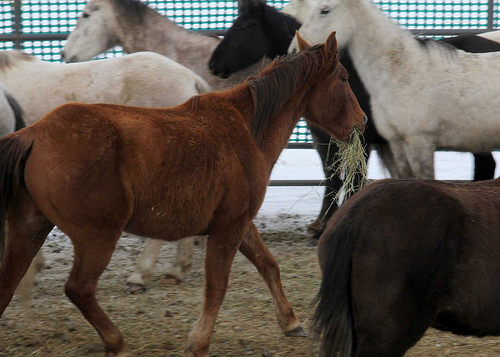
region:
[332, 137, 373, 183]
green grass hanging from horse's mouth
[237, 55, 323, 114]
brown horse's mane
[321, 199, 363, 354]
dark brown horse's tail on right of photo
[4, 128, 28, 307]
brown tail of horse on front of picture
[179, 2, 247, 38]
blue fencing in far back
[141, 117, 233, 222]
shaggy fur on horse's stomache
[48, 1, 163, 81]
back left white horse facing left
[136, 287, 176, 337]
light brown dirt on ground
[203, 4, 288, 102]
black horse in back right of photo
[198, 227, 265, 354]
right leg of front horse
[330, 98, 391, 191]
horse is carrying hay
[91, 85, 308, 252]
brown horse still has winter coat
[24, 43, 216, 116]
horse is white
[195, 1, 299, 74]
horse is dark brown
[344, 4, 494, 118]
horse is grayish color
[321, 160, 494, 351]
back side of the horse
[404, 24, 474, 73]
grayish horse has black mane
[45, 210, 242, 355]
horses are in the dirt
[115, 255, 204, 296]
hoofs of a horse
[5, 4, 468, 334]
group of horses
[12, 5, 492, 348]
A multicolored group of horses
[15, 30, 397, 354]
A brown horse eating hay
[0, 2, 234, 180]
Two white horses standing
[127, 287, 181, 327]
Small rocks on the ground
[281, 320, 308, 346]
The horse has grey hooves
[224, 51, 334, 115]
A brown horse's mane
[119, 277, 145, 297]
The white horse has brown hooves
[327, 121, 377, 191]
Hay in the horse's mouth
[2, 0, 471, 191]
A metal gate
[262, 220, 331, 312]
Dirt beneath the horses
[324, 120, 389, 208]
The horse has hay in its mouth.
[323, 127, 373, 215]
The hay is light green.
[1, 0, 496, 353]
A group of horses.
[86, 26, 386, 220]
This horse is reddish brown.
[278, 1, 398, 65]
This horse is white.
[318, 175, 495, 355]
This horse is brown.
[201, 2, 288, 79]
This horse is black.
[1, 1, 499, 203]
A fence is in the background.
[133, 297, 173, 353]
The ground is brown.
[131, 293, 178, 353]
The ground is dirt.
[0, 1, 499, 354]
six horses in a barn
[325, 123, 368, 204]
hay in the horse's mouth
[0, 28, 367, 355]
a brown horse among other horses in a barn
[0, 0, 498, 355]
white, brown, and black horses in a barn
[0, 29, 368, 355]
a brown horse walking in a barn while eating hay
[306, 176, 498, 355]
the rear and leg of a black horse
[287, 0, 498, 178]
a white horse standing beside a black horse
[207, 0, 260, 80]
the head of a black horse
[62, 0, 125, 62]
a white horse's head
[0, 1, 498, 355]
horses confined in a fenced barn